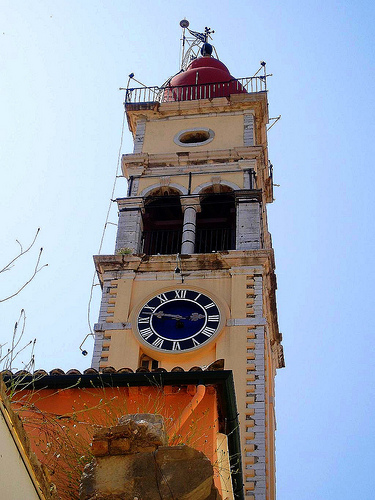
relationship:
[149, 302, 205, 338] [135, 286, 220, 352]
face of clock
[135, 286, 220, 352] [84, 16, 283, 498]
clock in tower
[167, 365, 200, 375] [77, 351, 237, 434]
roof shingles on roof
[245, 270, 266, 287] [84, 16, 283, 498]
brick on tower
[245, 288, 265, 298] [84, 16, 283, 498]
brick on tower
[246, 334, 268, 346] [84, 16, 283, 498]
brick on tower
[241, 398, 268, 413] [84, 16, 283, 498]
brick on tower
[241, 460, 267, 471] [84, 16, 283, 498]
brick on tower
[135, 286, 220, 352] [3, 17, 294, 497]
clock on building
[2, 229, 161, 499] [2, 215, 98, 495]
branches on tree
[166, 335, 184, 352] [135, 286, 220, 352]
numeral on clock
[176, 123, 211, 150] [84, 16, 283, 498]
window in tower